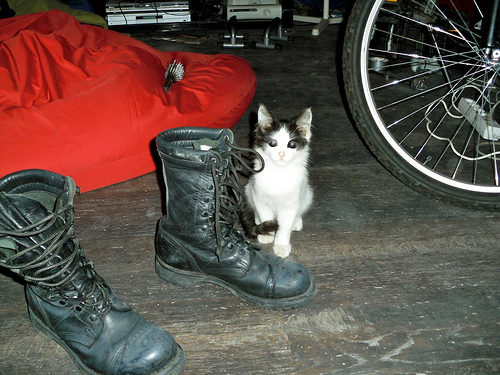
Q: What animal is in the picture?
A: Cat.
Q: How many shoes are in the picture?
A: 2.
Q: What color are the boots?
A: Black.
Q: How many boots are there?
A: Two.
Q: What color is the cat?
A: Black and white.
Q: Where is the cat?
A: On the floor.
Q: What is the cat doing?
A: Sitting.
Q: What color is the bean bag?
A: Red.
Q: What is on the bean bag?
A: A brush.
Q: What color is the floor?
A: Brown.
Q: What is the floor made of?
A: Wood.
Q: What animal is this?
A: Cat.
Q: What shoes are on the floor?
A: Combat boots.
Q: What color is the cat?
A: Black and white.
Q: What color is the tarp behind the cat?
A: Orange.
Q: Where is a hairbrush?
A: On the orange cover.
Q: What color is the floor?
A: Gray.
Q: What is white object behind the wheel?
A: Remote.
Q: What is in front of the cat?
A: A boot.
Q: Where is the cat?
A: Behind the boots.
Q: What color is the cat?
A: White and black.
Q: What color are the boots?
A: Black.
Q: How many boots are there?
A: Two.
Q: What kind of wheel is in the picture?
A: A bicycle wheel.